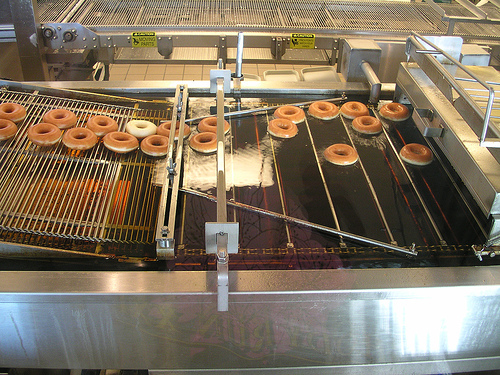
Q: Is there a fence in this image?
A: No, there are no fences.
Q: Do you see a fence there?
A: No, there are no fences.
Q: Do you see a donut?
A: Yes, there is a donut.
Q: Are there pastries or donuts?
A: Yes, there is a donut.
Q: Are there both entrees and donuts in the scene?
A: No, there is a donut but no entrees.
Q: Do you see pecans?
A: No, there are no pecans.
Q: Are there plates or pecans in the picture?
A: No, there are no pecans or plates.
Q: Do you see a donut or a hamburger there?
A: Yes, there is a donut.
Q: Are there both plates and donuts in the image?
A: No, there is a donut but no plates.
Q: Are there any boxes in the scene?
A: No, there are no boxes.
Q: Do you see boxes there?
A: No, there are no boxes.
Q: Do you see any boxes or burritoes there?
A: No, there are no boxes or burritoes.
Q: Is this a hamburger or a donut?
A: This is a donut.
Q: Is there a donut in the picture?
A: Yes, there is a donut.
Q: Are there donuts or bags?
A: Yes, there is a donut.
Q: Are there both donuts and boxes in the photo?
A: No, there is a donut but no boxes.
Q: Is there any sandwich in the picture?
A: No, there are no sandwiches.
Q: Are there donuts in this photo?
A: Yes, there is a donut.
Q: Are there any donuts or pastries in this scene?
A: Yes, there is a donut.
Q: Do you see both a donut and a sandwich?
A: No, there is a donut but no sandwiches.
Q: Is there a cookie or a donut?
A: Yes, there are donuts.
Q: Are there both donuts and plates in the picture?
A: No, there are donuts but no plates.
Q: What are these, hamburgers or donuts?
A: These are donuts.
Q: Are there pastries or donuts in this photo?
A: Yes, there is a donut.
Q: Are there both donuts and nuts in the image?
A: No, there is a donut but no nuts.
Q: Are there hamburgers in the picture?
A: No, there are no hamburgers.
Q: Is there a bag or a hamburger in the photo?
A: No, there are no hamburgers or bags.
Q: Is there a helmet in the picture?
A: No, there are no helmets.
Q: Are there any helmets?
A: No, there are no helmets.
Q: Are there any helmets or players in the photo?
A: No, there are no helmets or players.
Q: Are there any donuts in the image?
A: Yes, there is a donut.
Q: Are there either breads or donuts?
A: Yes, there is a donut.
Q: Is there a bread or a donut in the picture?
A: Yes, there is a donut.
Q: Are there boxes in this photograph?
A: No, there are no boxes.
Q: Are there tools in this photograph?
A: No, there are no tools.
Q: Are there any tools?
A: No, there are no tools.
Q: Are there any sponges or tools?
A: No, there are no tools or sponges.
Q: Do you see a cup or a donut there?
A: Yes, there is a donut.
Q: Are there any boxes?
A: No, there are no boxes.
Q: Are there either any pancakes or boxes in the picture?
A: No, there are no boxes or pancakes.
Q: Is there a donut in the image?
A: Yes, there is a donut.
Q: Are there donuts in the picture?
A: Yes, there is a donut.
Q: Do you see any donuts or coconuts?
A: Yes, there is a donut.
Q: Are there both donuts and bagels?
A: No, there is a donut but no bagels.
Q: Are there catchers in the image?
A: No, there are no catchers.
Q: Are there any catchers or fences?
A: No, there are no catchers or fences.